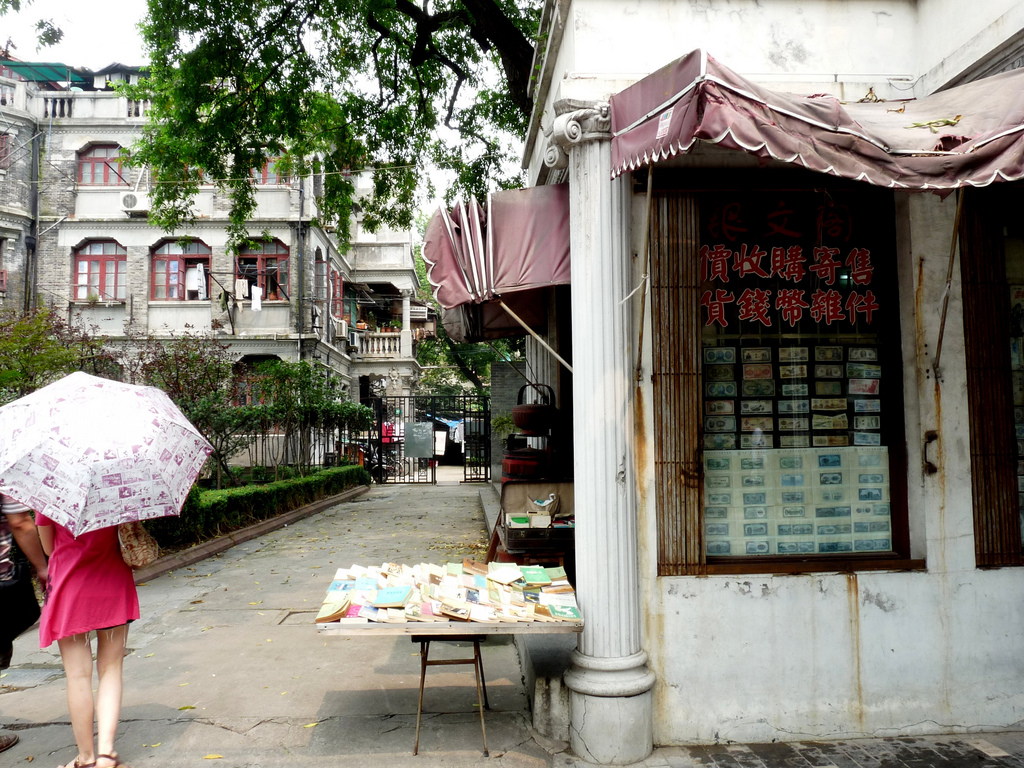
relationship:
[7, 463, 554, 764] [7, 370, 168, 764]
ground next to lady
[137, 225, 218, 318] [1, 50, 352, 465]
window on building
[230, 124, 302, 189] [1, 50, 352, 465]
window on building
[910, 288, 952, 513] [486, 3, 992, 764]
stain on building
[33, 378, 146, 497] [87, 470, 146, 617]
top of umbrella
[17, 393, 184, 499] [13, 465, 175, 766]
light umbrella over girl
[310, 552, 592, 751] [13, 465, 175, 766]
table next to girl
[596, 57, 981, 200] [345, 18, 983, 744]
awning over store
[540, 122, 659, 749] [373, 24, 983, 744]
pillar on building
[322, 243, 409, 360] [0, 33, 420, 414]
balcony on building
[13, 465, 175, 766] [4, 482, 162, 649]
girl with dress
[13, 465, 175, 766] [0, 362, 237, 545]
girl with light umbrella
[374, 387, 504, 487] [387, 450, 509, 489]
gate into alleyway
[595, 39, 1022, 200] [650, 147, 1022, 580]
awning over windows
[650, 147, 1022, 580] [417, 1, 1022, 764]
windows on store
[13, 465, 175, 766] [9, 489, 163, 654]
girl wears dress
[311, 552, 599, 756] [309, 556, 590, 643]
table has books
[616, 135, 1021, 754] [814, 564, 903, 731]
wall has rust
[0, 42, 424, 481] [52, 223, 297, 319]
building has windows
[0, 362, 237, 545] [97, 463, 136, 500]
light umbrella has pattern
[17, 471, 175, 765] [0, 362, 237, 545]
girl holding light umbrella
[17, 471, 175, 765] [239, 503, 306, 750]
girl in sidewalk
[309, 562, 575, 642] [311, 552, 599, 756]
papers on table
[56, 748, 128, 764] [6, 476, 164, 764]
sandals on woman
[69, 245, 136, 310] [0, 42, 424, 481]
window frames on building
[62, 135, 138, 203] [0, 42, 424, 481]
window frames on building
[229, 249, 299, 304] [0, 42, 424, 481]
window frames on building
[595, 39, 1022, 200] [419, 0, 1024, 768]
awning on store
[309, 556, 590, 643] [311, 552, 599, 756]
books cover table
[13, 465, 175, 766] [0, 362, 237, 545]
girl carrying light umbrella